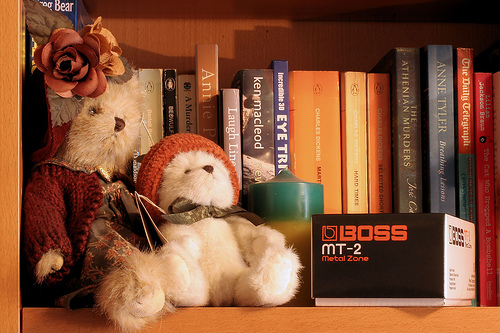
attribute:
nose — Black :
[111, 113, 130, 132]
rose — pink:
[27, 17, 130, 114]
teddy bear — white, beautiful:
[24, 14, 188, 328]